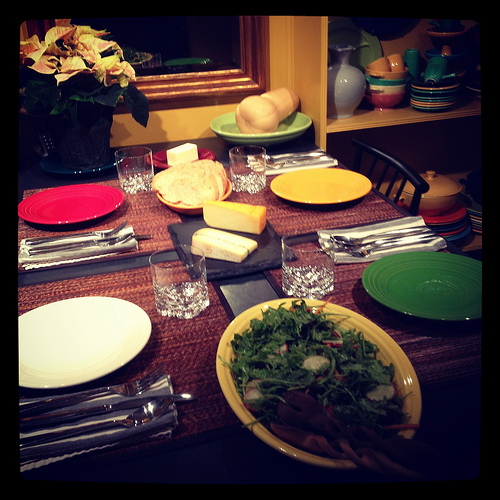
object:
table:
[18, 146, 482, 481]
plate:
[270, 168, 373, 205]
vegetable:
[235, 87, 299, 134]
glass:
[229, 145, 267, 195]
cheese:
[190, 227, 258, 264]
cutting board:
[167, 218, 298, 281]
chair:
[352, 138, 429, 217]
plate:
[361, 250, 483, 321]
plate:
[17, 184, 124, 224]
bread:
[154, 159, 227, 206]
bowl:
[156, 177, 232, 216]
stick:
[166, 142, 198, 166]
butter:
[166, 142, 198, 167]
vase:
[327, 43, 366, 120]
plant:
[19, 19, 153, 170]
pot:
[41, 106, 126, 174]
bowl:
[216, 298, 421, 468]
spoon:
[329, 224, 441, 258]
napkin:
[317, 215, 448, 264]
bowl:
[210, 111, 313, 147]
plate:
[18, 296, 153, 389]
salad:
[218, 299, 435, 485]